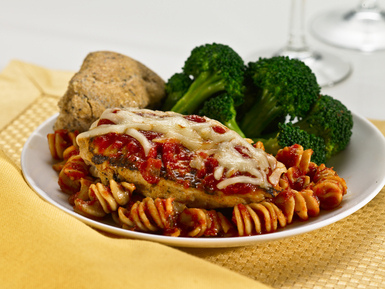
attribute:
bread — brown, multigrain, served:
[66, 49, 142, 109]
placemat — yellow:
[17, 208, 94, 266]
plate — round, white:
[345, 147, 384, 192]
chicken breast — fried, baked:
[121, 157, 197, 197]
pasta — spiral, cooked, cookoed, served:
[114, 192, 184, 232]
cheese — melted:
[139, 112, 158, 131]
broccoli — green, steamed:
[191, 46, 312, 136]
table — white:
[120, 9, 201, 63]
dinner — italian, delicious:
[106, 41, 298, 216]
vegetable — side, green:
[200, 40, 269, 117]